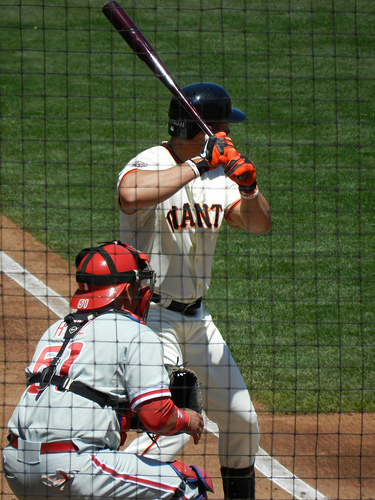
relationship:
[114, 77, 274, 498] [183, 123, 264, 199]
man wearing gloves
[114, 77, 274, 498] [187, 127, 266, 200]
man wearing gloves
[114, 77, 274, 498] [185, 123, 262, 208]
man wearing gloves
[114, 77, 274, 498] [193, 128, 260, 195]
man wearing gloves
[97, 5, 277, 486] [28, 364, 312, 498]
batter in box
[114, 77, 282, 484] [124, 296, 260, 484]
man wearing pants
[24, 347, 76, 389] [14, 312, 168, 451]
number on jersey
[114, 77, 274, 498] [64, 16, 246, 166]
man holds bat